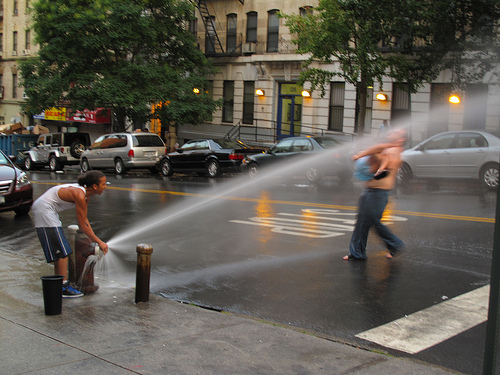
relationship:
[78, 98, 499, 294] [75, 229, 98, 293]
water outside of hydrant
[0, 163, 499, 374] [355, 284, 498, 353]
row has line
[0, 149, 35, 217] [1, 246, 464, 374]
cars next to sidewalk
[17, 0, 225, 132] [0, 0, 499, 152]
tree in front of building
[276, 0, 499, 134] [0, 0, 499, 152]
tree in front of building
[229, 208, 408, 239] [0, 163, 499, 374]
stop on top of row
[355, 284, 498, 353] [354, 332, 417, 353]
line has edge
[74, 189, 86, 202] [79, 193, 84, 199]
shoulder has part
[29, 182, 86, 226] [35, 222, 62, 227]
vest has edge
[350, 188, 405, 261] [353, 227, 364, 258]
jeans have part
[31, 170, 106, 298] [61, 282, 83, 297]
man has sneakers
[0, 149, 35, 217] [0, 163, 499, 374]
cars on side of row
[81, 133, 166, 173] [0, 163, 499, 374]
car on side of row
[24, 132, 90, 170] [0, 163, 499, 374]
car on side of row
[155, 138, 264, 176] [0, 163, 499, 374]
car on side of row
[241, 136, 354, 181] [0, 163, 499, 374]
car on side of row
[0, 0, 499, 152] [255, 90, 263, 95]
building has light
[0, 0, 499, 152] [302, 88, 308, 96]
building has light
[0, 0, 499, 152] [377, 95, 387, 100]
building has light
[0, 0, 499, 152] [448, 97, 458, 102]
building has light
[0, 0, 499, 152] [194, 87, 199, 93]
building has light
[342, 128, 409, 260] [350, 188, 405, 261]
man has jeans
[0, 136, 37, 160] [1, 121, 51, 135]
dumpster has boxes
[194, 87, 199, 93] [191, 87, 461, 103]
light in a row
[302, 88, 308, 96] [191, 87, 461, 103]
light in a row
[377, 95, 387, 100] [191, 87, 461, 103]
light in a row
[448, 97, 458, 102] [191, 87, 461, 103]
light in a row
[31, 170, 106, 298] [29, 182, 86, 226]
man has tank top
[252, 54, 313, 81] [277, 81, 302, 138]
awning on top of door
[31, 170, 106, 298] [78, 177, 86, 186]
man has ponytail